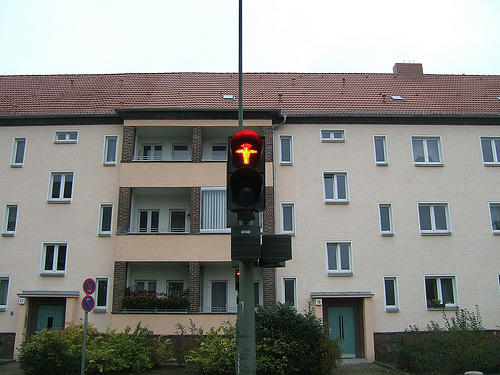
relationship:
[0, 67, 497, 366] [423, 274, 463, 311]
building has window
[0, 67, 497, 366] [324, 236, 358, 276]
building has window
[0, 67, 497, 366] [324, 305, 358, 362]
building has door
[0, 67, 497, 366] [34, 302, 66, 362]
building has door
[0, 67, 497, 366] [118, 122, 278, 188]
building has balcony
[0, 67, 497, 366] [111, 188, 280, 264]
building has balcony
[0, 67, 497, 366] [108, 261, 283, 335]
building has balcony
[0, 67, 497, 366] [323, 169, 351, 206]
building has window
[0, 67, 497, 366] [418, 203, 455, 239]
building has window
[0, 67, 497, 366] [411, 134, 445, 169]
building has window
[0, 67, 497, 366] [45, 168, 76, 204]
building has window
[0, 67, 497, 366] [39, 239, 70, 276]
building has window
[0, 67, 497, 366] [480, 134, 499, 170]
building has window